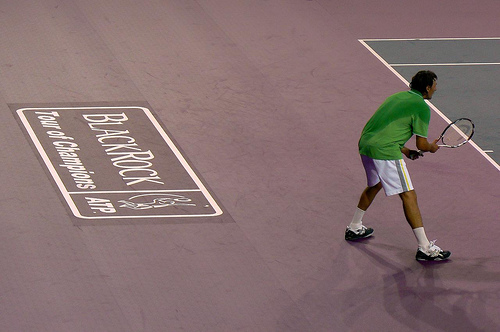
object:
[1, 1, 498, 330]
tennis court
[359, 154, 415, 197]
shorts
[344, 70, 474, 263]
man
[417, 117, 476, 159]
tennis racket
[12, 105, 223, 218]
logo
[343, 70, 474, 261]
tennis player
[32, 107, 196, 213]
letters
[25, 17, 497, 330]
tennisball.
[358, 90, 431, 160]
shirt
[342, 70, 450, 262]
man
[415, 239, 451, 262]
shoe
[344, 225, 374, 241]
shoe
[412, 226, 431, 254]
sock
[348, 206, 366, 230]
sock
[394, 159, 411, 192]
stripe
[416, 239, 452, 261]
tennis shoe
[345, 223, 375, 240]
tennis shoe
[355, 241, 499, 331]
shadow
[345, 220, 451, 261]
shoes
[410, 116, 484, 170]
racket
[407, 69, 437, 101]
hair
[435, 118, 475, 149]
racket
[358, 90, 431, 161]
green shirt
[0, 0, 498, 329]
court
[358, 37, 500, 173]
lines